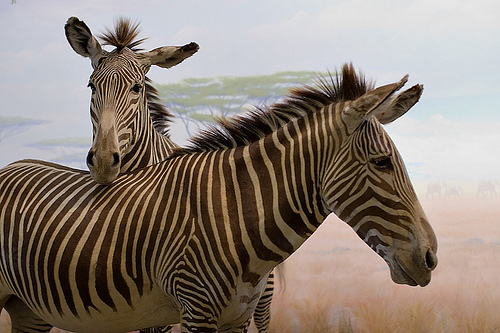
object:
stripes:
[172, 145, 271, 265]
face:
[323, 77, 438, 289]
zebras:
[0, 63, 439, 333]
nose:
[413, 243, 444, 274]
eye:
[369, 154, 394, 170]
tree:
[157, 70, 331, 137]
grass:
[291, 268, 492, 331]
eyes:
[127, 83, 145, 93]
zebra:
[63, 16, 200, 192]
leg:
[5, 291, 50, 331]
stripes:
[145, 121, 173, 157]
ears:
[379, 82, 422, 121]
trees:
[0, 102, 90, 166]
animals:
[422, 169, 493, 206]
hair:
[167, 60, 374, 161]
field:
[275, 209, 494, 328]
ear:
[345, 77, 407, 118]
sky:
[183, 6, 471, 70]